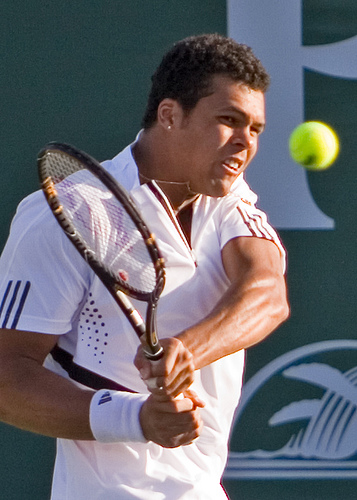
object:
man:
[0, 34, 292, 499]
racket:
[34, 140, 167, 389]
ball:
[288, 120, 341, 171]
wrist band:
[90, 388, 148, 446]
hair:
[141, 33, 271, 131]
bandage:
[144, 377, 157, 389]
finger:
[144, 364, 181, 389]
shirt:
[0, 128, 284, 500]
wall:
[1, 1, 355, 498]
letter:
[224, 0, 356, 234]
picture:
[220, 338, 356, 483]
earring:
[166, 125, 173, 132]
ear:
[154, 96, 177, 133]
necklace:
[137, 169, 199, 199]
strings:
[46, 153, 158, 290]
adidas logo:
[98, 388, 112, 406]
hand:
[130, 334, 198, 402]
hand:
[143, 383, 206, 450]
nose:
[233, 127, 256, 150]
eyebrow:
[216, 103, 248, 117]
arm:
[175, 236, 291, 370]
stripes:
[1, 280, 31, 330]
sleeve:
[1, 195, 89, 333]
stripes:
[238, 206, 274, 241]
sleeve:
[220, 182, 290, 274]